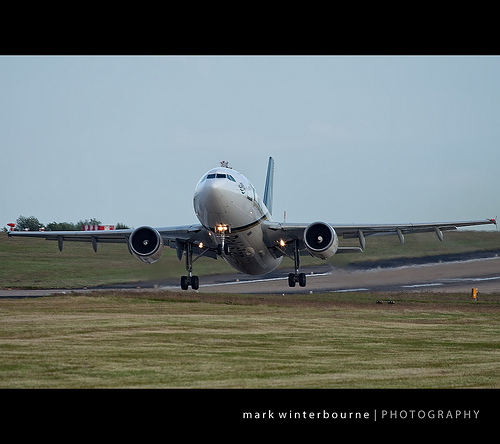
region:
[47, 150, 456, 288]
plane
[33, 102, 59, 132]
white clouds in blue sky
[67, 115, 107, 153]
white clouds in blue sky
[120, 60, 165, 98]
white clouds in blue sky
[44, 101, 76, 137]
white clouds in blue sky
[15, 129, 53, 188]
white clouds in blue sky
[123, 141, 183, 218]
white clouds in blue sky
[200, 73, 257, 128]
white clouds in blue sky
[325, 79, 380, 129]
white clouds in blue sky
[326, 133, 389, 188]
white clouds in blue sky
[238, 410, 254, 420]
white lower case letter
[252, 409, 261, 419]
white lower case letter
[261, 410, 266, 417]
white lower case letter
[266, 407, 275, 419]
white lower case letter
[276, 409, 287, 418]
white lower case letter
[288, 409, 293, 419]
white lower case letter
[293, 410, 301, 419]
white lower case letter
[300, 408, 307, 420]
white lower case letter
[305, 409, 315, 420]
white lower case letter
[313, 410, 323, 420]
white lower case letter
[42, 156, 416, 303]
white plane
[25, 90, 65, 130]
white clouds in blue sky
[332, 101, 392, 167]
white clouds in blue sky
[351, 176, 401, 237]
white clouds in blue sky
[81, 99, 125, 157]
white clouds in blue sky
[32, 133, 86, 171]
white clouds in blue sky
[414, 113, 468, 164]
white clouds in blue sky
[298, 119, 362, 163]
white clouds in blue sky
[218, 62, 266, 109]
white clouds in blue sky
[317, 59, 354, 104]
white clouds in blue sky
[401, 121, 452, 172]
white clouds in blue sky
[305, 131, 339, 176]
white clouds in blue sky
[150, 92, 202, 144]
white clouds in blue sky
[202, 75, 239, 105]
white clouds in blue sky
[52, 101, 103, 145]
white clouds in blue sky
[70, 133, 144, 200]
white clouds in blue sky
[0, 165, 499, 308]
A large airplane taking off from the runway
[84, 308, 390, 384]
Short green grass grows on the ground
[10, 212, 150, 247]
A line of trees in the distance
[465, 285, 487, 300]
An orange traffic cone on the ground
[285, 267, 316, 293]
Two small black wheels on the ground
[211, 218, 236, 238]
A small yellow light on the plane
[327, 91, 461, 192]
An open blue sky behind the plane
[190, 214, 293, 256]
Multiple lights on the underside of the plane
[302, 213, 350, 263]
An engine of the plane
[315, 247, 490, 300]
The runway behind the plane